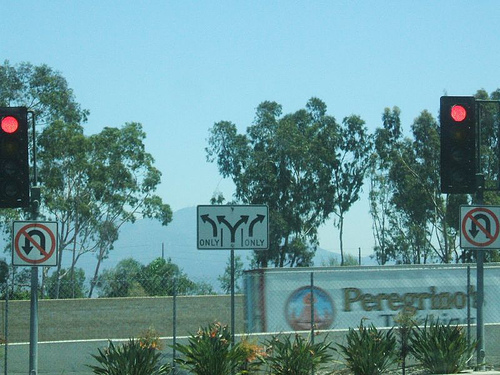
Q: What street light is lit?
A: Red light.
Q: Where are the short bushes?
A: Next to chain link fence.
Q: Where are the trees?
A: Across dirt field.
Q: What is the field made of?
A: Dirt.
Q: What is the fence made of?
A: Metal.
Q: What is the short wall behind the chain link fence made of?
A: Concrete.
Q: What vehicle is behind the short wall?
A: Semi truck.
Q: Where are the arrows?
A: On street signs.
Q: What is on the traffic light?
A: Red light.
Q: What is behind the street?
A: The wall.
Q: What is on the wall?
A: The sign.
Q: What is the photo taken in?
A: Montana.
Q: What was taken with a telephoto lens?
A: The photo was.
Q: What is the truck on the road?
A: White.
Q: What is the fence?
A: Chain link.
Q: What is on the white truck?
A: A huge logo and a brand name.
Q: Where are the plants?
A: Near the metallic fence.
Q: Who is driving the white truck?
A: A truck driver.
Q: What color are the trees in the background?
A: Green.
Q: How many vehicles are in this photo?
A: One.